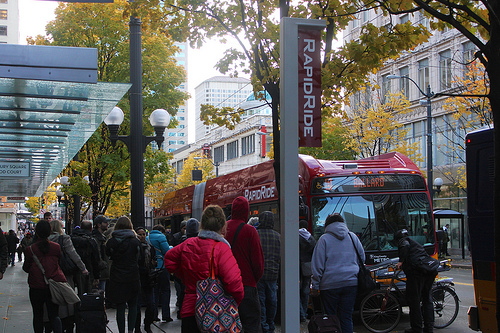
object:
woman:
[163, 205, 246, 331]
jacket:
[160, 229, 245, 318]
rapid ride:
[241, 185, 279, 202]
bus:
[150, 151, 439, 321]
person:
[387, 228, 447, 333]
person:
[218, 195, 268, 332]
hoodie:
[217, 196, 266, 289]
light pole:
[127, 8, 147, 245]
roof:
[0, 42, 134, 201]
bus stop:
[0, 2, 333, 333]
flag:
[295, 23, 326, 148]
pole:
[277, 12, 305, 328]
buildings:
[337, 1, 492, 251]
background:
[0, 0, 500, 332]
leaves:
[366, 78, 384, 88]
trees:
[385, 2, 498, 332]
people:
[103, 213, 144, 332]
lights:
[317, 170, 323, 179]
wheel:
[360, 289, 404, 332]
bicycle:
[357, 269, 459, 333]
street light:
[103, 104, 129, 151]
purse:
[192, 240, 247, 333]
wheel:
[420, 286, 463, 328]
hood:
[230, 196, 250, 219]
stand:
[0, 43, 136, 320]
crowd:
[21, 191, 436, 332]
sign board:
[294, 25, 325, 149]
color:
[296, 33, 322, 145]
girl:
[21, 219, 69, 332]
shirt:
[21, 241, 65, 289]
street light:
[146, 107, 177, 147]